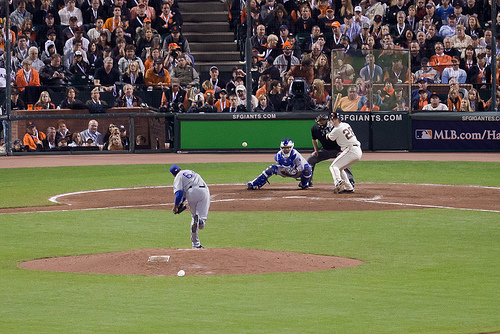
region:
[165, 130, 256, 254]
a pitcher pitches a baseball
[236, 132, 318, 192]
a catcher is waiting to catch the baseball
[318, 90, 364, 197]
a batter is ready to hit a baseball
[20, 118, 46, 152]
a sitting man wearing an orange jacket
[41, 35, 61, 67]
a woman wearing a winter hat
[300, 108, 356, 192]
an umpire watching the incoming pitch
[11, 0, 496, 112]
baseball fans watching a baseball game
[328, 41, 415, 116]
a wire fence to protect spectators from the ball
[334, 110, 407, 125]
the San Francisco Giants website URL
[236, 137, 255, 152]
the pitched baseball in midair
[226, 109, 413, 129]
San Francisco Giants web site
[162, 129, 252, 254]
Pitcher throws speedy ball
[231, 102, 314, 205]
Catcher ready incoming ball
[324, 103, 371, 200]
Batter stance hit baseball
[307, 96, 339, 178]
Umpire call ball no hit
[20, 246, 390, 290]
Pitcher's mound middle diamond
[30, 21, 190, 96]
Fans populate bleachers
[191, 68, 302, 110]
Spectators crowd close wall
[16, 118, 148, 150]
Dugout players media wait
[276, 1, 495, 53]
All fans wait ball hit miss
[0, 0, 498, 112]
fans are watching the game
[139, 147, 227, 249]
the man's uniform is white and blue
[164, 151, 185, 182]
the man's hat is blue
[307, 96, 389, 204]
the player is holding a bat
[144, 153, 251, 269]
the player threw the ball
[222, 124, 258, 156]
the ball is white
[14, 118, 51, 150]
the man is wearing an orange shirt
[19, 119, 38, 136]
the man's hat is black and orange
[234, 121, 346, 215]
the catcher is wearing protective gear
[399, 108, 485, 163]
the letters says mlb.com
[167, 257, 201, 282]
a white plastic cup laying on the baseball field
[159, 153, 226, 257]
pitcher for the baseball game throwing the ball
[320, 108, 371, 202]
batter getting ready to hit the ball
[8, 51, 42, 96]
a lady in the crowd wearing an orange jacket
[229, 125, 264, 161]
baseball flying in the air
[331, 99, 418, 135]
advertisement for the giants website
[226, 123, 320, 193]
catcher getting ready to possibly catch the ball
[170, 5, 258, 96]
stairs going up the stadium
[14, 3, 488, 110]
a staduim with seats full of people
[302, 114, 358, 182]
umpire in black shirt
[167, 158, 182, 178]
the head of a pitcher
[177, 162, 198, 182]
a number on the pitcher's uniform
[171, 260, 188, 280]
a white bag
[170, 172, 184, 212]
the arm of a pitcher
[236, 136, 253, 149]
a white baseball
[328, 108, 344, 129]
the head of the hitter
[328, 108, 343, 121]
a black batting helmet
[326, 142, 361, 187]
the legs of the hitter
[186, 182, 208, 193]
a black belt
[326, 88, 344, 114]
a brown baseball bat